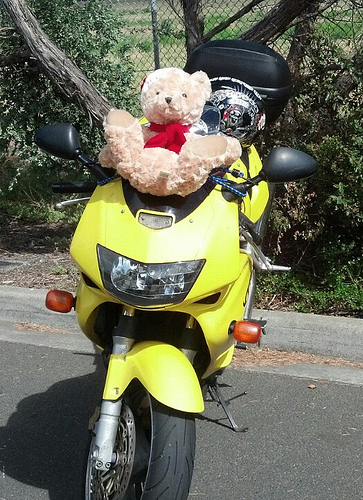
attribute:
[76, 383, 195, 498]
wheel — black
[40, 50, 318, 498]
motorcycle — yellow 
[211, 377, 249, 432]
kickstand — gray, down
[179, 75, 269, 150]
helmet — design-decorated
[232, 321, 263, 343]
red light — signal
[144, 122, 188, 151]
scarf — red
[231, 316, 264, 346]
light — orange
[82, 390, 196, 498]
wheel — black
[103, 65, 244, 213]
teddy bear — brown